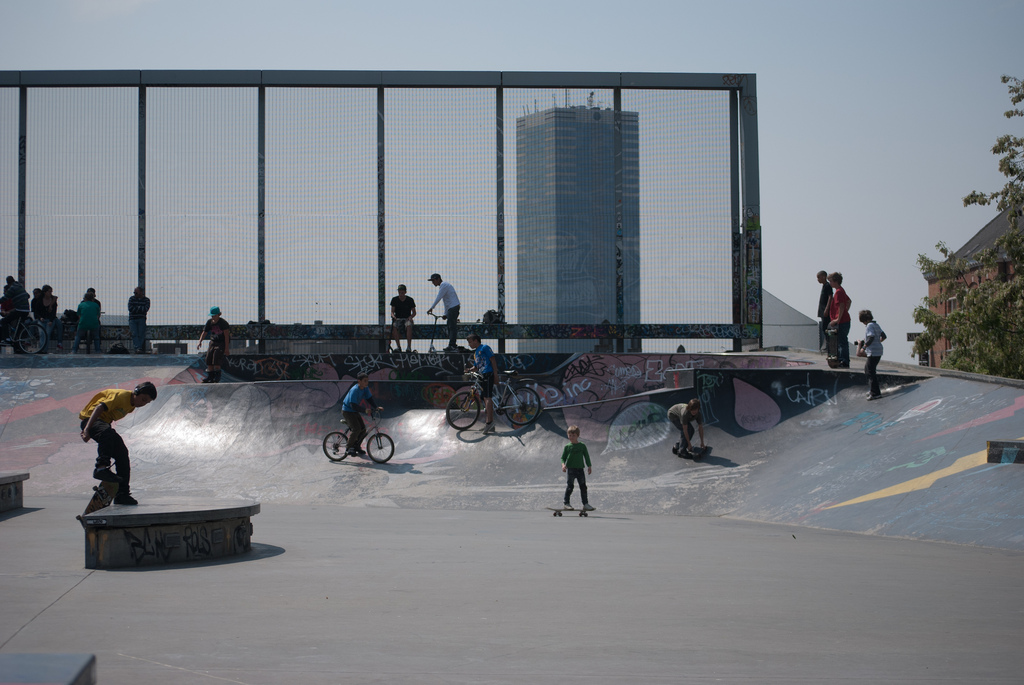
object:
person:
[464, 334, 500, 433]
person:
[390, 284, 416, 353]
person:
[827, 272, 852, 368]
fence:
[0, 70, 764, 355]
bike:
[323, 409, 395, 464]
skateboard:
[687, 438, 709, 460]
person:
[79, 381, 157, 505]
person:
[427, 273, 461, 351]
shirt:
[390, 295, 416, 318]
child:
[341, 373, 384, 455]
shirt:
[79, 389, 136, 424]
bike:
[446, 370, 541, 430]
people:
[817, 270, 852, 367]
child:
[667, 398, 706, 459]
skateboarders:
[76, 480, 596, 526]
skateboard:
[76, 481, 119, 526]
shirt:
[342, 383, 373, 412]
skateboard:
[546, 507, 597, 517]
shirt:
[560, 442, 592, 469]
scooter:
[428, 313, 465, 353]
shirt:
[430, 281, 461, 315]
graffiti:
[693, 370, 1024, 511]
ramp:
[874, 462, 1024, 549]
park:
[693, 351, 1014, 377]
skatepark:
[0, 70, 1024, 685]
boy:
[561, 424, 594, 510]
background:
[0, 354, 1024, 685]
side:
[790, 346, 1024, 387]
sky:
[0, 0, 1024, 366]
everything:
[0, 70, 1024, 380]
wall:
[562, 353, 815, 405]